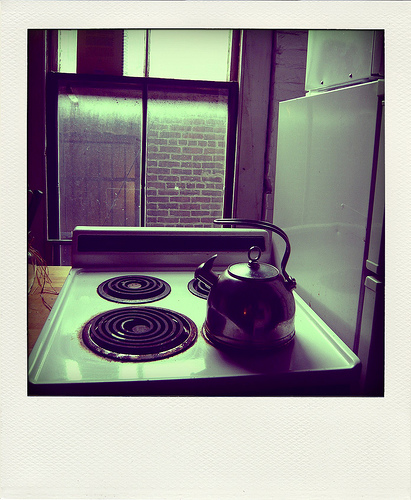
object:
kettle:
[193, 215, 297, 355]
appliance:
[302, 29, 384, 95]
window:
[52, 30, 148, 240]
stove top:
[26, 265, 362, 387]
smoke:
[33, 261, 72, 291]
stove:
[26, 259, 362, 398]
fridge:
[270, 75, 384, 397]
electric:
[81, 303, 199, 365]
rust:
[96, 345, 155, 365]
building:
[43, 27, 236, 245]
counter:
[70, 224, 272, 271]